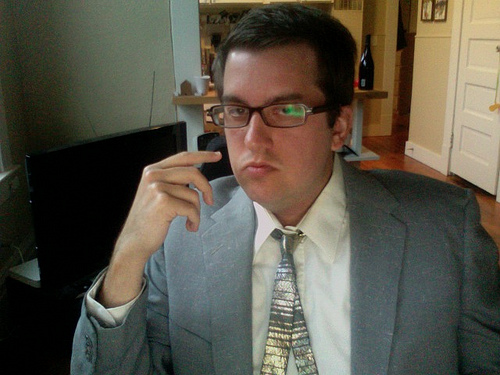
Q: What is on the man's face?
A: Glasses.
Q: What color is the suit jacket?
A: Grey.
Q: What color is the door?
A: White.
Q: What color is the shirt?
A: White.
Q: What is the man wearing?
A: A shirt, suit coat and tie.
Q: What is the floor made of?
A: Wood.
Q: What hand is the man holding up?
A: Right hand.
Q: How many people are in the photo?
A: 1.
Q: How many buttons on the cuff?
A: 2.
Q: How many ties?
A: 1.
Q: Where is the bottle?
A: Behind man.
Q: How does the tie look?
A: Shiny.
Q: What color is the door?
A: White.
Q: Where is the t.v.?
A: Behind man.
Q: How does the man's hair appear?
A: Short.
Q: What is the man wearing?
A: Glasses.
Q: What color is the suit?
A: Gray.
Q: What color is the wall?
A: Yellow.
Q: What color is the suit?
A: Gray.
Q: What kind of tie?
A: Unkempt.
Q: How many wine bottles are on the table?
A: 1.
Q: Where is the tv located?
A: Behind the man.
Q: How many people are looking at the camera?
A: 1.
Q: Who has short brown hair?
A: The man.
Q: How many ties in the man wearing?
A: 1.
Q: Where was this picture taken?
A: Inside a house.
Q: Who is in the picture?
A: A man.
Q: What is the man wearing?
A: A suit and tie.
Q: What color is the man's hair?
A: Black.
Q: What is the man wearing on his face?
A: Glasses.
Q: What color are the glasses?
A: Black.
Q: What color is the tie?
A: Silver.